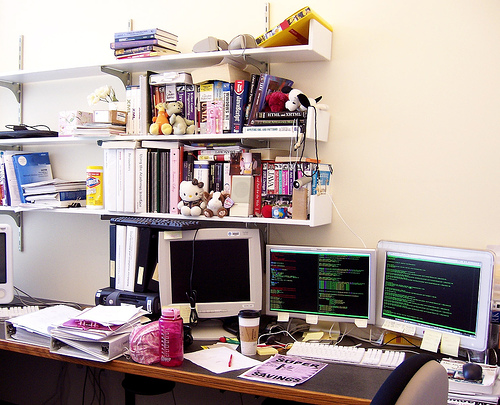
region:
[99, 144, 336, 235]
Hello kitty on bookshelf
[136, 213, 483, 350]
three computer screens in a row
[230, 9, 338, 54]
yellow box on top shelf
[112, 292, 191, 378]
pink water bottle on desk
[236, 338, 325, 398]
super savings ad on desk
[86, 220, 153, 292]
four binders next to screens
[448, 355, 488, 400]
mouse on top of books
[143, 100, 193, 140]
two stuffed animals on the shelf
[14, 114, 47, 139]
pair of shoes on the shelf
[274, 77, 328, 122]
black and white snoopy toy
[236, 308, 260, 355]
white coffee cup with black lid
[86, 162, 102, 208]
yellow container of clorox wipes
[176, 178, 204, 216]
white stuffed kitty on the shelf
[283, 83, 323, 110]
black and white stuffed dog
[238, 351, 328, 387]
paper on desk that says Super Savings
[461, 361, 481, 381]
black computer mouse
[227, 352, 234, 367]
red ink pen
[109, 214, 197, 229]
keyboard on top of binders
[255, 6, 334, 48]
yellow book on top shelf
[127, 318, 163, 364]
pink and white makeup case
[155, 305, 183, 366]
Pink water bottle sitting on desk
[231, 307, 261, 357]
Carryout cup of coffee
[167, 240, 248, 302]
Monitor screen of computer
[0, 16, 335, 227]
White shelf attached to the wall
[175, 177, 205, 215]
White stuffed animal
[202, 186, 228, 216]
Brown and white stuffed animal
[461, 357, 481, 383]
Black mouse sitting on top of desk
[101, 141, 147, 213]
White notebooks sitting on white shelf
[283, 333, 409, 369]
White computer keyboard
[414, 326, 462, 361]
Note-its attached to front of monitor screen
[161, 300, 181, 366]
this is a bottle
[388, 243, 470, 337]
this is the screen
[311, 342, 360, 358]
this the keyboard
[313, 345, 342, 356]
these are the keys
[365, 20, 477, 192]
this is the wall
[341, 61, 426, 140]
the wall is white in color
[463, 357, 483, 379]
this is the mouse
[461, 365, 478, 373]
the mouse is black in color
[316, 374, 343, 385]
this is a table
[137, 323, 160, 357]
this is a bag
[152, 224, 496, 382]
three computer screens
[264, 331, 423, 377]
white wide computer keyboard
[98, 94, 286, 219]
stuffed pets on shelves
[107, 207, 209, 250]
black keyboard sits on binders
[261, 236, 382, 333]
computer screen is on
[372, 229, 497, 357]
computer screen is on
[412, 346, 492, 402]
black mouse sitting on books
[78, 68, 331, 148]
book sitting on shelf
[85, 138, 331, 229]
binders sitting on shelf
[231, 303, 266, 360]
hot drink sitting on brown and dark brown table